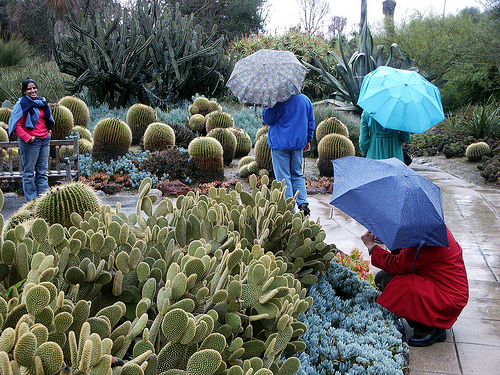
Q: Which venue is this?
A: This is a garden.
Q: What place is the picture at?
A: It is at the garden.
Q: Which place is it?
A: It is a garden.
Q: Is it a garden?
A: Yes, it is a garden.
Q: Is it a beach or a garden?
A: It is a garden.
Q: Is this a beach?
A: No, it is a garden.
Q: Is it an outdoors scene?
A: Yes, it is outdoors.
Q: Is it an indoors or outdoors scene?
A: It is outdoors.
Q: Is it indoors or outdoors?
A: It is outdoors.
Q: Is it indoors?
A: No, it is outdoors.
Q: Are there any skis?
A: No, there are no skis.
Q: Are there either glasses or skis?
A: No, there are no skis or glasses.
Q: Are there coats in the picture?
A: Yes, there is a coat.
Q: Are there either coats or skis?
A: Yes, there is a coat.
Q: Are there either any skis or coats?
A: Yes, there is a coat.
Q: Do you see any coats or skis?
A: Yes, there is a coat.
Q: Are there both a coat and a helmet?
A: No, there is a coat but no helmets.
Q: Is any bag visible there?
A: No, there are no bags.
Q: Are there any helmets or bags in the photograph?
A: No, there are no bags or helmets.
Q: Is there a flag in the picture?
A: No, there are no flags.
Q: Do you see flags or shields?
A: No, there are no flags or shields.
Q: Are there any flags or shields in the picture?
A: No, there are no flags or shields.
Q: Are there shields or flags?
A: No, there are no flags or shields.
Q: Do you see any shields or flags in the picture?
A: No, there are no flags or shields.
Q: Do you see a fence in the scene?
A: No, there are no fences.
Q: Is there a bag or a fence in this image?
A: No, there are no fences or bags.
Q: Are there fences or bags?
A: No, there are no fences or bags.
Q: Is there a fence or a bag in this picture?
A: No, there are no fences or bags.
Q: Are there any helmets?
A: No, there are no helmets.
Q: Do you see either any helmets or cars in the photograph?
A: No, there are no helmets or cars.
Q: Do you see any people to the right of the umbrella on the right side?
A: No, the person is to the left of the umbrella.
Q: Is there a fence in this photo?
A: No, there are no fences.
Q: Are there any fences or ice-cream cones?
A: No, there are no fences or ice-cream cones.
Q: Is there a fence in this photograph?
A: No, there are no fences.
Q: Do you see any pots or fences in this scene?
A: No, there are no fences or pots.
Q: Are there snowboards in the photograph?
A: No, there are no snowboards.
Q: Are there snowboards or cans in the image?
A: No, there are no snowboards or cans.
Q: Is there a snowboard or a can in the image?
A: No, there are no snowboards or cans.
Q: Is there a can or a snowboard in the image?
A: No, there are no snowboards or cans.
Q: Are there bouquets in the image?
A: No, there are no bouquets.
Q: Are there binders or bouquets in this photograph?
A: No, there are no bouquets or binders.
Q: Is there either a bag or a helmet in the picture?
A: No, there are no helmets or bags.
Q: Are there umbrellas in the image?
A: Yes, there is an umbrella.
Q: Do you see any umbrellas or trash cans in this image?
A: Yes, there is an umbrella.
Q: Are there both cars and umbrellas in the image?
A: No, there is an umbrella but no cars.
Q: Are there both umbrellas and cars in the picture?
A: No, there is an umbrella but no cars.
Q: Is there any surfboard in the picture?
A: No, there are no surfboards.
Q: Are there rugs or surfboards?
A: No, there are no surfboards or rugs.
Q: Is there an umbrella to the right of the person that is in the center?
A: Yes, there is an umbrella to the right of the person.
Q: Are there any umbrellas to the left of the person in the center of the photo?
A: No, the umbrella is to the right of the person.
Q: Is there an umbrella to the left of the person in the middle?
A: No, the umbrella is to the right of the person.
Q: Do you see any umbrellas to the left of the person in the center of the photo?
A: No, the umbrella is to the right of the person.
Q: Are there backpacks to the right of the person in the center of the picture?
A: No, there is an umbrella to the right of the person.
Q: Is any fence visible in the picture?
A: No, there are no fences.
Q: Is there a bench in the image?
A: Yes, there is a bench.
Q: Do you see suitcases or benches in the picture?
A: Yes, there is a bench.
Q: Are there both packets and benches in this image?
A: No, there is a bench but no packets.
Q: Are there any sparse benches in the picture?
A: Yes, there is a sparse bench.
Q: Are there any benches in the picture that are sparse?
A: Yes, there is a bench that is sparse.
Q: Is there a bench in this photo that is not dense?
A: Yes, there is a sparse bench.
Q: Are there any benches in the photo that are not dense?
A: Yes, there is a sparse bench.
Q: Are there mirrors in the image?
A: No, there are no mirrors.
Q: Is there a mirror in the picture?
A: No, there are no mirrors.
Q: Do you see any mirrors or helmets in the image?
A: No, there are no mirrors or helmets.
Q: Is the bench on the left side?
A: Yes, the bench is on the left of the image.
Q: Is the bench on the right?
A: No, the bench is on the left of the image.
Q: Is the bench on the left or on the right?
A: The bench is on the left of the image.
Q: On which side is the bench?
A: The bench is on the left of the image.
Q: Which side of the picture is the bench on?
A: The bench is on the left of the image.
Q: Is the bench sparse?
A: Yes, the bench is sparse.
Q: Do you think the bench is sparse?
A: Yes, the bench is sparse.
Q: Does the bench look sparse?
A: Yes, the bench is sparse.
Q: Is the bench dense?
A: No, the bench is sparse.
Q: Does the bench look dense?
A: No, the bench is sparse.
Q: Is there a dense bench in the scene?
A: No, there is a bench but it is sparse.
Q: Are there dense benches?
A: No, there is a bench but it is sparse.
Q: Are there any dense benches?
A: No, there is a bench but it is sparse.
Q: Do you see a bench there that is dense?
A: No, there is a bench but it is sparse.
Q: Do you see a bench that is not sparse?
A: No, there is a bench but it is sparse.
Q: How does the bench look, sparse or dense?
A: The bench is sparse.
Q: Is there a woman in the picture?
A: Yes, there is a woman.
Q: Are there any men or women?
A: Yes, there is a woman.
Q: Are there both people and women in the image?
A: Yes, there are both a woman and people.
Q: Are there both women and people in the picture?
A: Yes, there are both a woman and people.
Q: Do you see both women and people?
A: Yes, there are both a woman and people.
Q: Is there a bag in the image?
A: No, there are no bags.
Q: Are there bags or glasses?
A: No, there are no bags or glasses.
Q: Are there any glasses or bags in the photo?
A: No, there are no bags or glasses.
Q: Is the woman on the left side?
A: Yes, the woman is on the left of the image.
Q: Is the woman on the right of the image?
A: No, the woman is on the left of the image.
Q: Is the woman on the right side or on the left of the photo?
A: The woman is on the left of the image.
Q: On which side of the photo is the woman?
A: The woman is on the left of the image.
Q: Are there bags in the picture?
A: No, there are no bags.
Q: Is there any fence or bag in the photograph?
A: No, there are no bags or fences.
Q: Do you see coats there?
A: Yes, there is a coat.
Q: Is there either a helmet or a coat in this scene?
A: Yes, there is a coat.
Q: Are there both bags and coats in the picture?
A: No, there is a coat but no bags.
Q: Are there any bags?
A: No, there are no bags.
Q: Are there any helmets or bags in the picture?
A: No, there are no bags or helmets.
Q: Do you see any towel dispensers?
A: No, there are no towel dispensers.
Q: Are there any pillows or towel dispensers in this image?
A: No, there are no towel dispensers or pillows.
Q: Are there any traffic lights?
A: No, there are no traffic lights.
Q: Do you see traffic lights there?
A: No, there are no traffic lights.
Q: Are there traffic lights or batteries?
A: No, there are no traffic lights or batteries.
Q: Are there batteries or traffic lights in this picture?
A: No, there are no traffic lights or batteries.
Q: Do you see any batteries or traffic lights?
A: No, there are no traffic lights or batteries.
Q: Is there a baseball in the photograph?
A: No, there are no baseballs.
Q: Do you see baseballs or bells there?
A: No, there are no baseballs or bells.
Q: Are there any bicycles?
A: No, there are no bicycles.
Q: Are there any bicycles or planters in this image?
A: No, there are no bicycles or planters.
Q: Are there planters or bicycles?
A: No, there are no bicycles or planters.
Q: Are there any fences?
A: No, there are no fences.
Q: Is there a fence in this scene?
A: No, there are no fences.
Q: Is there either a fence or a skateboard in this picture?
A: No, there are no fences or skateboards.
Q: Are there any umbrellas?
A: Yes, there is an umbrella.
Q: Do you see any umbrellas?
A: Yes, there is an umbrella.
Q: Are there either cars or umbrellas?
A: Yes, there is an umbrella.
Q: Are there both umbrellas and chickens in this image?
A: No, there is an umbrella but no chickens.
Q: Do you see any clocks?
A: No, there are no clocks.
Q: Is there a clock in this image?
A: No, there are no clocks.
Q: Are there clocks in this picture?
A: No, there are no clocks.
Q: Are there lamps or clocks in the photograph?
A: No, there are no clocks or lamps.